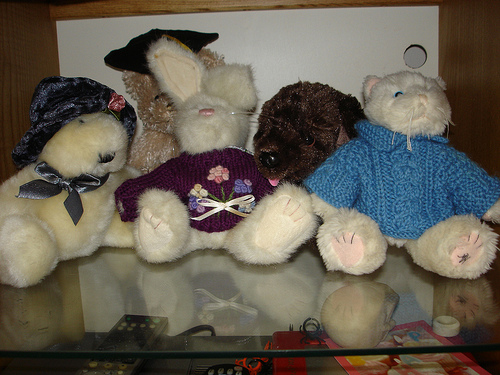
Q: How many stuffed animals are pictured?
A: Five.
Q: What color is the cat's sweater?
A: Blue.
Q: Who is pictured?
A: No One.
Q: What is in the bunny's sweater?
A: Flowers.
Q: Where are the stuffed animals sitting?
A: On the table.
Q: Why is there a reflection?
A: Glass.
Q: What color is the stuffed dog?
A: Brown.